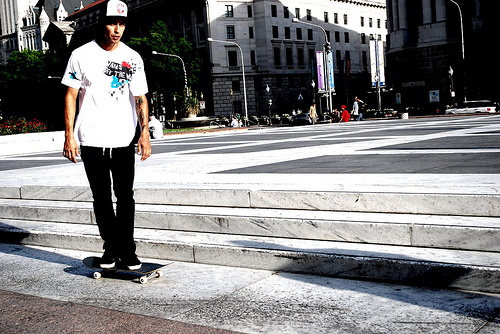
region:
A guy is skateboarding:
[60, 1, 173, 290]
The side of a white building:
[207, 0, 390, 119]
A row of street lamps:
[46, 0, 467, 127]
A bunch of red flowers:
[1, 113, 49, 134]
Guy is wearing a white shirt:
[59, 0, 155, 162]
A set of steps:
[1, 180, 499, 299]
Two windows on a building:
[220, 2, 242, 42]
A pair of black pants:
[77, 141, 139, 256]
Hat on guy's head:
[95, 0, 133, 45]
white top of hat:
[104, 1, 129, 19]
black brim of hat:
[104, 13, 134, 24]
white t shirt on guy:
[61, 35, 141, 149]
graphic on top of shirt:
[107, 61, 131, 93]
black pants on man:
[87, 145, 139, 292]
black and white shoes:
[102, 245, 149, 270]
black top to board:
[75, 241, 165, 283]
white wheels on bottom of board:
[134, 271, 164, 281]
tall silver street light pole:
[155, 42, 180, 63]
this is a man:
[40, 13, 220, 302]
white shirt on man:
[55, 18, 168, 156]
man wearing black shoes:
[88, 245, 153, 282]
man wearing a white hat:
[95, 5, 140, 22]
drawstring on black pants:
[92, 135, 120, 163]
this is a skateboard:
[74, 237, 165, 282]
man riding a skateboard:
[48, 2, 210, 302]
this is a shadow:
[223, 196, 475, 324]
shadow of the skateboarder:
[8, 188, 122, 296]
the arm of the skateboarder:
[61, 40, 87, 160]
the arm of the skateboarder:
[129, 49, 151, 159]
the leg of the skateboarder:
[81, 143, 119, 256]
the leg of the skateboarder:
[110, 146, 143, 252]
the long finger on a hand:
[140, 141, 145, 158]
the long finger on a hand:
[70, 146, 76, 161]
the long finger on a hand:
[142, 144, 147, 159]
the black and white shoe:
[98, 246, 115, 268]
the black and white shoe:
[121, 252, 141, 268]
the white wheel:
[90, 271, 100, 279]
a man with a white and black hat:
[95, 1, 136, 28]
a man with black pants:
[75, 140, 146, 251]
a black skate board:
[82, 251, 177, 285]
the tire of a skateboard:
[134, 268, 166, 285]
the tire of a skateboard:
[85, 264, 117, 281]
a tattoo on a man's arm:
[132, 92, 149, 131]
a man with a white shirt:
[59, 41, 148, 153]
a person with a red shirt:
[338, 108, 353, 123]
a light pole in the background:
[150, 49, 199, 129]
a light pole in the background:
[203, 33, 255, 127]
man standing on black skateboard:
[58, 1, 160, 269]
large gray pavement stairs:
[4, 183, 499, 293]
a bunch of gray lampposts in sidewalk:
[44, 0, 466, 126]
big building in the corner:
[64, 2, 384, 129]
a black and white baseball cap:
[95, 0, 134, 20]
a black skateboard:
[85, 250, 170, 283]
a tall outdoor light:
[203, 32, 255, 118]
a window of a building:
[226, 20, 236, 41]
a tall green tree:
[125, 18, 205, 110]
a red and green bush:
[25, 114, 50, 134]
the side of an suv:
[442, 95, 497, 115]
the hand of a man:
[63, 138, 81, 163]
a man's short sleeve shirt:
[62, 41, 149, 152]